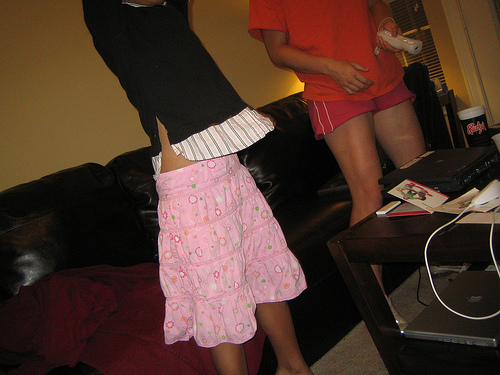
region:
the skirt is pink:
[151, 159, 353, 370]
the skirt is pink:
[138, 173, 218, 285]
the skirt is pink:
[164, 170, 268, 334]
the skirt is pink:
[208, 215, 318, 362]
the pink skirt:
[145, 161, 304, 348]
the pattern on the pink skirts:
[180, 215, 259, 288]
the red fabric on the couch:
[73, 290, 153, 349]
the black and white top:
[86, 7, 273, 159]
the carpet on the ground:
[332, 351, 364, 373]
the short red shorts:
[303, 71, 420, 131]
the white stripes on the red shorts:
[309, 95, 333, 133]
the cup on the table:
[458, 102, 490, 152]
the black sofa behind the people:
[100, 70, 430, 332]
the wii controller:
[375, 20, 420, 52]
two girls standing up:
[71, 0, 426, 370]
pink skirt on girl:
[125, 171, 301, 343]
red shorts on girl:
[300, 89, 436, 132]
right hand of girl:
[288, 51, 365, 94]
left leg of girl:
[251, 295, 308, 373]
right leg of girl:
[194, 320, 239, 373]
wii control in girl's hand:
[363, 28, 419, 58]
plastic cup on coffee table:
[449, 100, 484, 146]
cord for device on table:
[415, 267, 487, 324]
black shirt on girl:
[116, 2, 248, 161]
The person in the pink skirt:
[75, 1, 312, 373]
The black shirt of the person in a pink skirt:
[79, 1, 272, 171]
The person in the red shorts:
[246, 1, 430, 224]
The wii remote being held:
[371, 18, 427, 63]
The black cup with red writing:
[456, 103, 493, 150]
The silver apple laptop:
[395, 270, 499, 347]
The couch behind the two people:
[1, 59, 453, 374]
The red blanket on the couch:
[5, 254, 272, 374]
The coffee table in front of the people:
[319, 113, 499, 374]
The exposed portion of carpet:
[304, 265, 457, 374]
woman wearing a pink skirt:
[129, 155, 311, 336]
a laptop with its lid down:
[399, 260, 499, 360]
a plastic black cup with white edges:
[454, 104, 499, 143]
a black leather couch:
[2, 160, 159, 265]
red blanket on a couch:
[3, 260, 160, 372]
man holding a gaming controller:
[368, 13, 422, 73]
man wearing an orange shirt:
[253, 2, 431, 94]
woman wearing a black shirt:
[75, 13, 233, 128]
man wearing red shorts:
[300, 81, 433, 132]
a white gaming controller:
[458, 176, 498, 228]